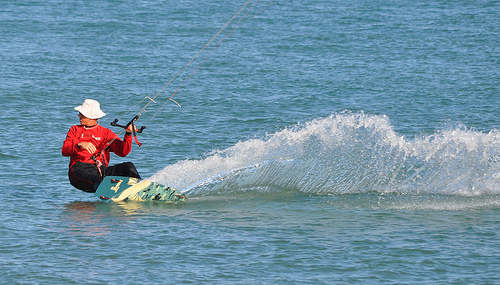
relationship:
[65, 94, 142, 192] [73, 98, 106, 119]
man wearing hat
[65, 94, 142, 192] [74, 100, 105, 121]
man wearing white hat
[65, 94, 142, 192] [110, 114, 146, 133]
man holding handles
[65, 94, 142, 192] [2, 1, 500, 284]
man in water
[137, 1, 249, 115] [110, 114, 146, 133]
rope attached to handles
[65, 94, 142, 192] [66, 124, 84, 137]
man looking over shoulder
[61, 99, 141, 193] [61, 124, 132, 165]
surfer wearing red shirt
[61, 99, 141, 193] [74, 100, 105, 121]
surfer wearing white hat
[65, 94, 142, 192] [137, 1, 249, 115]
man holding rope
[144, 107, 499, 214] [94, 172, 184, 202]
wave behind surfboard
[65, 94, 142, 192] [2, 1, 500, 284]
man riding on water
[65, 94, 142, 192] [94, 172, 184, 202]
man riding surfboard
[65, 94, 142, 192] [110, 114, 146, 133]
man holds handles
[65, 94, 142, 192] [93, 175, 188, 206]
man standing on board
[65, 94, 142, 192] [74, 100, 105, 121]
man wearing a white hat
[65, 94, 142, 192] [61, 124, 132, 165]
man wearing red shirt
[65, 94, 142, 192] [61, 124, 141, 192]
man wearing a wetsuit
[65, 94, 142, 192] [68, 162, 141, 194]
man wearing black pants